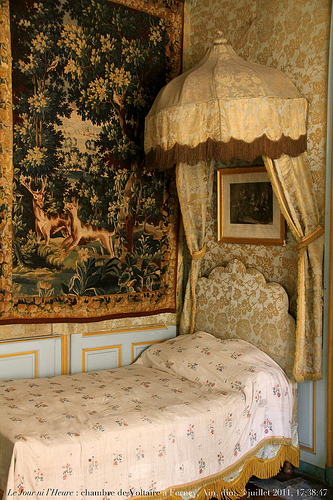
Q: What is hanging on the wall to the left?
A: Tapestry.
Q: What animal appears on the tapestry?
A: Deer.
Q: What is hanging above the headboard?
A: Picture.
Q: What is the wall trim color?
A: Gold.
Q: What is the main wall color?
A: White.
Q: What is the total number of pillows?
A: 2.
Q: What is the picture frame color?
A: Brown.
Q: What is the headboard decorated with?
A: Flowers.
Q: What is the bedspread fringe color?
A: Gold.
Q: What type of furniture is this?
A: A bed.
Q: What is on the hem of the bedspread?
A: Yellow trim.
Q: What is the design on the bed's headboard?
A: Yellow flowers.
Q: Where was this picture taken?
A: A bedroom.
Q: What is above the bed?
A: Canopy.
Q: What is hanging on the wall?
A: Tapestry.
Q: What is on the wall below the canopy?
A: A painting.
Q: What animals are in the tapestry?
A: Deer.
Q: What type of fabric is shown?
A: Brocade.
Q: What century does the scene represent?
A: 18th.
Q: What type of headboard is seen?
A: Fabric.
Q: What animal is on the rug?
A: Deer.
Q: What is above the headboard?
A: Picture.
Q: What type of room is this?
A: Bedroom.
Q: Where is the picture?
A: Wall.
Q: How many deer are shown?
A: Two.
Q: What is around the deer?
A: Trees.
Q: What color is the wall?
A: Yellow and white.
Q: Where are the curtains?
A: Head of the bed.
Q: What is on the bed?
A: Spread.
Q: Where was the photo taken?
A: In a bedroom.